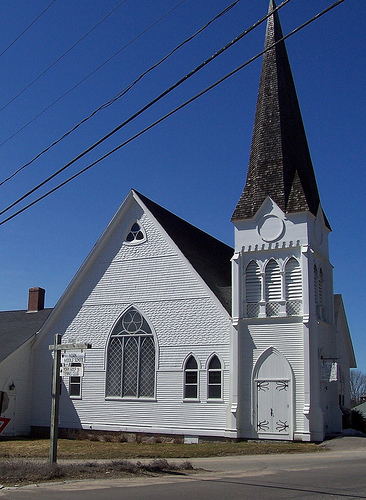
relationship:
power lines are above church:
[1, 1, 337, 226] [1, 3, 357, 447]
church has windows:
[1, 3, 357, 447] [205, 351, 222, 404]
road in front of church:
[3, 436, 365, 499] [1, 3, 357, 447]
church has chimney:
[1, 3, 357, 447] [25, 279, 46, 315]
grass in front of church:
[3, 426, 332, 488] [1, 3, 357, 447]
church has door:
[1, 3, 357, 447] [247, 347, 300, 442]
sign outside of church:
[58, 347, 87, 376] [1, 3, 357, 447]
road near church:
[3, 436, 365, 499] [1, 3, 357, 447]